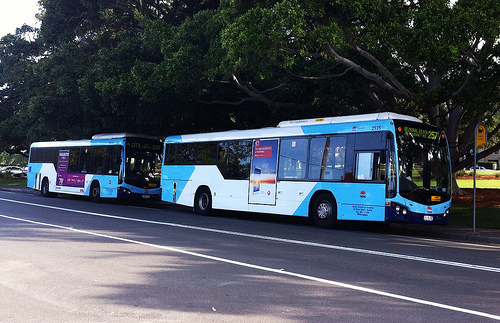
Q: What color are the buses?
A: Blue and white.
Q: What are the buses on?
A: The road.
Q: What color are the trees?
A: Green.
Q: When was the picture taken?
A: Daytime.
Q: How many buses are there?
A: Two.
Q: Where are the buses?
A: On the road.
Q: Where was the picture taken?
A: In a metropolitan area bus stop.